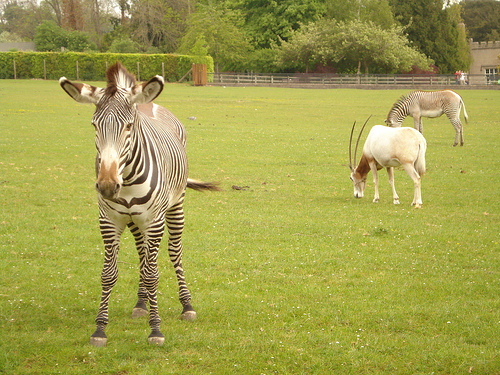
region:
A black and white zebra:
[56, 60, 205, 354]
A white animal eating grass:
[344, 110, 428, 211]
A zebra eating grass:
[382, 84, 470, 149]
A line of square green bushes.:
[1, 49, 214, 88]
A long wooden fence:
[205, 69, 461, 86]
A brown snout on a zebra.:
[96, 161, 120, 201]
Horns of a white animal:
[348, 115, 370, 168]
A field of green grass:
[0, 77, 498, 367]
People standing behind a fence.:
[451, 70, 467, 84]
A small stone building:
[466, 34, 498, 88]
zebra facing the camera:
[78, 67, 163, 349]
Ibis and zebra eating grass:
[336, 70, 474, 215]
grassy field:
[270, 225, 476, 350]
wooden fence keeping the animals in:
[187, 54, 499, 92]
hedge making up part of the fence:
[3, 41, 216, 87]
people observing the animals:
[451, 64, 472, 91]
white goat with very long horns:
[331, 109, 449, 211]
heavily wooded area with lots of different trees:
[33, 9, 455, 68]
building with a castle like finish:
[458, 28, 494, 92]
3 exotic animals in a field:
[18, 37, 498, 342]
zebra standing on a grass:
[48, 55, 220, 350]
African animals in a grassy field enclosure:
[38, 62, 475, 362]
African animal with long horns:
[324, 110, 436, 217]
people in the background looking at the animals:
[443, 62, 475, 92]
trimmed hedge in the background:
[0, 42, 222, 108]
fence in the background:
[4, 51, 499, 113]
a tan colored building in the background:
[441, 14, 498, 86]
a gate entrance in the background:
[173, 50, 227, 97]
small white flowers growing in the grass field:
[233, 276, 389, 373]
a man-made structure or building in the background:
[1, 20, 102, 93]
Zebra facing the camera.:
[36, 65, 233, 334]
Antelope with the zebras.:
[321, 105, 433, 218]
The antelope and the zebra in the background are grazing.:
[293, 59, 474, 228]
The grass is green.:
[263, 260, 443, 337]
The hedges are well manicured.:
[11, 48, 223, 92]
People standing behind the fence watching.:
[438, 63, 478, 93]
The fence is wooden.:
[219, 61, 379, 93]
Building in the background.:
[456, 25, 498, 86]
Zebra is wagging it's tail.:
[184, 165, 225, 207]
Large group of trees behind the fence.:
[188, 7, 443, 74]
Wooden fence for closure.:
[205, 65, 476, 90]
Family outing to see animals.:
[446, 60, 484, 93]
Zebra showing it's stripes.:
[45, 67, 211, 347]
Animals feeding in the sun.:
[306, 66, 486, 224]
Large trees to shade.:
[181, 11, 453, 71]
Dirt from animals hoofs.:
[216, 175, 301, 211]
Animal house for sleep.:
[456, 27, 496, 74]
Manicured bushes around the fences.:
[0, 60, 220, 68]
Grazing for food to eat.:
[321, 116, 389, 218]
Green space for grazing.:
[263, 268, 491, 367]